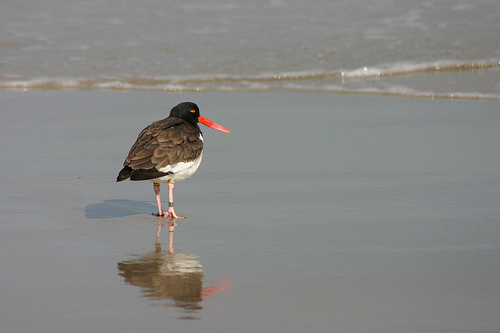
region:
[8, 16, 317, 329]
a bird standing in the water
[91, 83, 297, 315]
a bird standing in a body of water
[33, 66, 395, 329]
a body of water with a bird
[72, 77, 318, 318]
a bird in the water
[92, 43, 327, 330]
a bird standing in shallow water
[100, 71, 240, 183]
a bird with a long beak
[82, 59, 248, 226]
a bird with a long orange beak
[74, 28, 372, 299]
a body of water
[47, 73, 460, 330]
a body of shallow water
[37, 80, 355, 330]
a bird in a body of shallow water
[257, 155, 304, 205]
part of a water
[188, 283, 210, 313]
part of a sjade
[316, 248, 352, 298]
part of a water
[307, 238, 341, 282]
part of a water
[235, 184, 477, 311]
The sand on the beach is wet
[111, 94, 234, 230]
The bird is standing on the beach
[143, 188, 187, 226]
The legs of the bird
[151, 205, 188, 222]
The feet of the bird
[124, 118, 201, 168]
The feathers on the bird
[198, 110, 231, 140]
The beak of the bird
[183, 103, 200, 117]
The eye of the bird is red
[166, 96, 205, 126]
The head of the bird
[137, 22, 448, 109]
The water on the beach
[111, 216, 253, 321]
The shadow of the bird on the beach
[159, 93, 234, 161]
bird's head is black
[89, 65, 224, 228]
bird's head is black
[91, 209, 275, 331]
a bird's reflection on the ground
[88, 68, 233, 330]
a bird's reflection on the ground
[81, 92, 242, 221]
brown bird walking on wet sand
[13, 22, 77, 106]
wet sand on beach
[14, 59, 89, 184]
wet brown sand on beach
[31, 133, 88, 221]
wet brown sand on beach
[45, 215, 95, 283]
wet brown sand on beach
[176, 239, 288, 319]
wet brown sand on beach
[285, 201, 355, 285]
wet brown sand on beach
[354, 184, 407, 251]
wet brown sand on beach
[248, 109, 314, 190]
wet brown sand on beach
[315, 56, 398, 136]
wet brown sand on beach